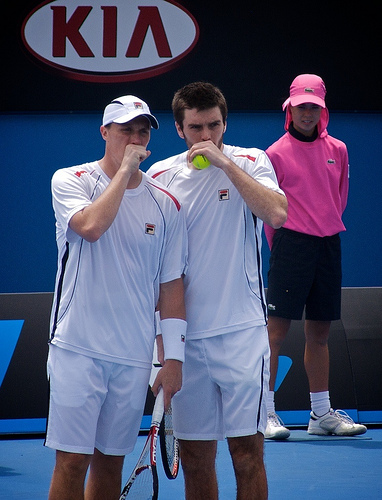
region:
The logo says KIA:
[22, 0, 213, 92]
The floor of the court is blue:
[279, 446, 337, 496]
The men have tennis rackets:
[123, 361, 203, 496]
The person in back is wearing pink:
[264, 59, 370, 247]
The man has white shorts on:
[53, 338, 142, 456]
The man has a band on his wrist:
[153, 310, 198, 402]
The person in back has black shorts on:
[255, 205, 372, 379]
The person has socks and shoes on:
[297, 372, 379, 475]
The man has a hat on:
[74, 78, 176, 161]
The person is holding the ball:
[179, 144, 211, 172]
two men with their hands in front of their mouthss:
[35, 84, 277, 499]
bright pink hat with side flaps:
[270, 66, 337, 144]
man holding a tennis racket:
[36, 88, 187, 494]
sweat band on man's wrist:
[152, 310, 195, 384]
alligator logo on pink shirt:
[320, 155, 339, 168]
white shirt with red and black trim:
[32, 151, 195, 373]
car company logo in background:
[15, 1, 212, 83]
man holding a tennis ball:
[164, 82, 289, 245]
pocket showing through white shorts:
[39, 335, 100, 415]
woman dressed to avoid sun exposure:
[259, 66, 356, 350]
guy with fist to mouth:
[40, 86, 186, 289]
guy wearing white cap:
[88, 83, 171, 167]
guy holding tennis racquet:
[56, 88, 194, 499]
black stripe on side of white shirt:
[46, 168, 181, 358]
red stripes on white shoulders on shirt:
[43, 151, 195, 304]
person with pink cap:
[260, 56, 341, 149]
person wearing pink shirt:
[268, 74, 376, 252]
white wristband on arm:
[140, 294, 210, 404]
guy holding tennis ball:
[171, 81, 253, 196]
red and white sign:
[26, 5, 204, 74]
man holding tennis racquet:
[141, 397, 162, 489]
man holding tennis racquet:
[155, 419, 181, 476]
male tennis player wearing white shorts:
[40, 349, 142, 460]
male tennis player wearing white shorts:
[186, 337, 266, 439]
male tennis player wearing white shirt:
[58, 175, 155, 362]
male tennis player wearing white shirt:
[185, 178, 254, 325]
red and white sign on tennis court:
[16, 7, 207, 80]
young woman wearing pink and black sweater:
[281, 142, 349, 226]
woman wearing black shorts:
[274, 232, 346, 319]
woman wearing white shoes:
[306, 407, 367, 443]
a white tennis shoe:
[307, 408, 371, 440]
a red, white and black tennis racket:
[122, 390, 173, 499]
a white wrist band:
[159, 317, 194, 368]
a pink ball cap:
[279, 66, 340, 114]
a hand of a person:
[119, 137, 154, 167]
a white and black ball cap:
[98, 93, 162, 125]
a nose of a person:
[197, 122, 213, 144]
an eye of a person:
[184, 122, 204, 134]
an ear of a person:
[170, 117, 186, 143]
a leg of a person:
[302, 304, 335, 405]